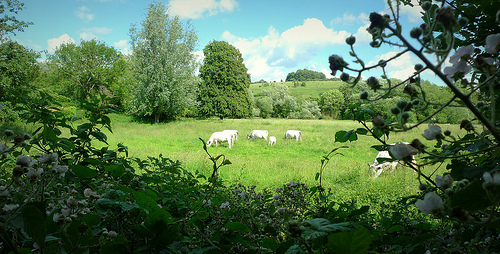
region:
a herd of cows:
[190, 118, 412, 187]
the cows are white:
[198, 115, 314, 172]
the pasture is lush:
[164, 126, 361, 182]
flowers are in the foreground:
[6, 107, 158, 248]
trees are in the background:
[88, 10, 346, 120]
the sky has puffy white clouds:
[258, 8, 333, 65]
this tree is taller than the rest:
[130, 0, 205, 140]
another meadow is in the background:
[266, 80, 341, 102]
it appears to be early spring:
[58, 37, 483, 237]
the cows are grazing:
[179, 109, 336, 168]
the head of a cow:
[362, 157, 390, 184]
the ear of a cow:
[374, 160, 384, 173]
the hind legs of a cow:
[223, 135, 234, 147]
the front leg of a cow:
[211, 138, 219, 150]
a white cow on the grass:
[201, 123, 242, 153]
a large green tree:
[193, 32, 259, 118]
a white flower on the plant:
[385, 136, 423, 164]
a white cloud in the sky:
[44, 28, 79, 58]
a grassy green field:
[1, 111, 499, 233]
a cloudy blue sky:
[0, 0, 499, 92]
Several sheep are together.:
[179, 115, 324, 155]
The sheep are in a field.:
[102, 105, 431, 181]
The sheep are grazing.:
[155, 108, 327, 171]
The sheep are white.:
[190, 115, 319, 163]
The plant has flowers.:
[319, 5, 499, 222]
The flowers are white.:
[426, 34, 483, 89]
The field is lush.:
[90, 114, 435, 196]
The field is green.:
[77, 118, 424, 179]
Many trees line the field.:
[31, 2, 261, 122]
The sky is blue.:
[0, 2, 367, 72]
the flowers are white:
[337, 47, 468, 207]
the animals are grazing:
[189, 115, 319, 160]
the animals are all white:
[186, 116, 311, 169]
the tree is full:
[196, 28, 252, 120]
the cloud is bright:
[274, 17, 337, 60]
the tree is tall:
[122, 4, 197, 124]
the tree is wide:
[43, 35, 120, 82]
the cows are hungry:
[188, 102, 320, 170]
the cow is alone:
[351, 141, 411, 187]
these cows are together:
[194, 115, 310, 158]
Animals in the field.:
[181, 93, 484, 188]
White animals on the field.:
[196, 107, 337, 193]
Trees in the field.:
[112, 19, 299, 167]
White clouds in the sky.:
[235, 16, 380, 91]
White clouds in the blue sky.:
[205, 30, 332, 80]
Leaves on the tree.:
[312, 92, 498, 217]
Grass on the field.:
[150, 109, 364, 181]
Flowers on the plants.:
[12, 145, 135, 212]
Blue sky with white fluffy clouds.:
[61, 17, 419, 96]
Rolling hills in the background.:
[82, 2, 444, 156]